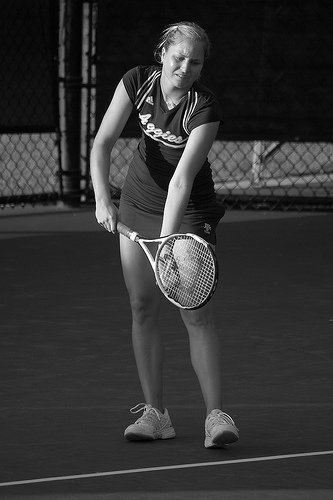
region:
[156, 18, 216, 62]
girl has light hair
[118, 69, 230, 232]
girl wears solid color dress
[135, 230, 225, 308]
girl has two tone racket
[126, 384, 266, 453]
girl has white shoes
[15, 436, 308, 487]
white line on tennis court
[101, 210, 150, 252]
dark handle on racket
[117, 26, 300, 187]
dark fence behind girl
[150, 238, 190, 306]
tennis ball in left hand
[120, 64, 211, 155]
stripes on girl's dress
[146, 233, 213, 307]
logo on tennis racket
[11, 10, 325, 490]
Picture is in black and white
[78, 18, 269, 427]
This is a female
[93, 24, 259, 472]
The woman is playing tennis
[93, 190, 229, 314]
Woman holding a tennis racket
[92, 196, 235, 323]
Tennis racket in her right hand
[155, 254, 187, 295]
Tennis ball is in her left hand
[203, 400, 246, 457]
Left toes are off of the ground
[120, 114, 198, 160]
Woman plays for the Aggies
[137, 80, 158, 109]
Woman's shirt made by Adidas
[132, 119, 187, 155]
name of school on dress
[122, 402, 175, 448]
shoe on the player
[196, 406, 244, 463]
shoe on the player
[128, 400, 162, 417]
laces on the player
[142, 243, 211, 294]
tennis racquet in hand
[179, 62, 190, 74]
nose of the player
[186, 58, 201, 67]
eye of the player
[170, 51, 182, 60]
eye of the player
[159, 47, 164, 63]
ear of the player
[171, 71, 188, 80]
mouth of the player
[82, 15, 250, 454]
A woman is playing tennis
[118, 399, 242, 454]
A pair of sneakers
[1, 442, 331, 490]
White line on the court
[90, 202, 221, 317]
Tennis racket in a hand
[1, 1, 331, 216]
A fence behind the tennis player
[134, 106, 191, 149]
White writing on a shirt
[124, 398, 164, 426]
Shoelaces on a sneaker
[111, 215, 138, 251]
Handle of a racket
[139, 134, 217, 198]
A shadow on the shirt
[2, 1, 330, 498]
Woman is standing on a tennis court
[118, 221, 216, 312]
a tennis racket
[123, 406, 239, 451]
white shoes with gray bottoms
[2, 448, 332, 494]
white line on the tennis court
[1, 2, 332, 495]
black and white photo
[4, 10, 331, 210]
a chain link fence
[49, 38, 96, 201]
metal fence fosts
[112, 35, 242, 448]
a woman wearing a black outfit with black sneakers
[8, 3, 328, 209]
a wire fence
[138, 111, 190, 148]
the word Aggies in white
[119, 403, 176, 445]
the shoe is white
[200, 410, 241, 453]
shoe is white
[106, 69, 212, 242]
a black dress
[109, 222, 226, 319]
a tennis racket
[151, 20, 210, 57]
hair is blonde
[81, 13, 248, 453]
A lady is playing tennis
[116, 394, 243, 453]
A pair of white sneakers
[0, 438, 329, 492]
White line on tennis court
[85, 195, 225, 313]
A tennis racket in a hand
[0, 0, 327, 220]
A fence behind tennis player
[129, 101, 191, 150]
White writing on a shirt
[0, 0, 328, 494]
Tennis player standing on a tennis court